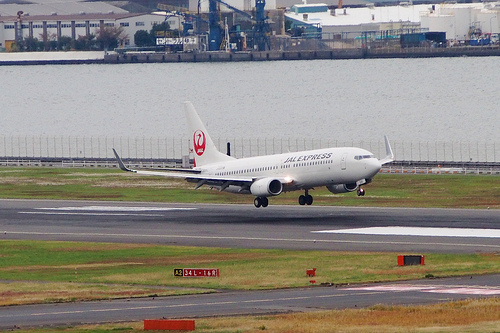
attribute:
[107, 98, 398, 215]
jet — white red, taking off, black, in the air, white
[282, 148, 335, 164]
lettering — black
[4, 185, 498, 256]
runway — black top, black, grey, paved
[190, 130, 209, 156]
symbol — red, white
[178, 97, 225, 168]
tail — white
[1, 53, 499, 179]
wall — tall, white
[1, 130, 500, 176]
fence — short, metal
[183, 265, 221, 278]
sign — small, red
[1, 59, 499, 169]
water — grey